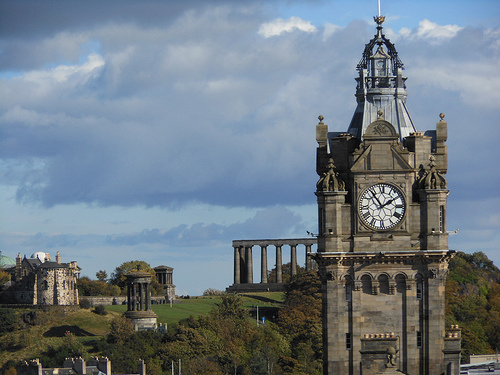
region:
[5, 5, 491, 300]
A blue, cloudy sky.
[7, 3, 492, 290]
Blue sky with grey and white clouds.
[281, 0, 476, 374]
A clock tower.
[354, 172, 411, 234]
Clock reading 1:55 p.m.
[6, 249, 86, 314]
Historic building in the background.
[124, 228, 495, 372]
Trees behind the clock tower.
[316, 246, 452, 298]
Ornamental architecture on the clock tower.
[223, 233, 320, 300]
Historic landmark near the clock tower.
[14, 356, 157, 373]
A row of chimneys.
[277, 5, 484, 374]
A tower featuring a round clock.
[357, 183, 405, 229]
A clock on the tower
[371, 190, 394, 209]
Hands on the clock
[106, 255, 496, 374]
Trees behind the tower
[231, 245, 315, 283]
Pillars behind the trees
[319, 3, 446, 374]
A stone tower in front of trees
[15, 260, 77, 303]
A stone building near the grassy field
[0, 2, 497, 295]
A cloudy sky above the tower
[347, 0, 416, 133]
A tower above the clock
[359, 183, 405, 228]
The clock has roman numerals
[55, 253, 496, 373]
The trees are near the grassy field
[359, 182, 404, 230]
clock on tower side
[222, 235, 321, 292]
tall pillars that are gray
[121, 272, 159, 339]
round pillars in a circle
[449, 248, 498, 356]
trees with green leaves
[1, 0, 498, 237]
clouds with blue sky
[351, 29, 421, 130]
decorative top on tower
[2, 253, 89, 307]
building on top of a hill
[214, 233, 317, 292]
columns on top of hill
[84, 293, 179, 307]
brick wall on hill top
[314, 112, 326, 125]
round sphere on top of tower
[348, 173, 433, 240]
its is 2oclcok on the clock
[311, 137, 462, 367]
the buidling is grey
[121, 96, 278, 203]
clouds are in the sky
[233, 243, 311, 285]
the pillars are six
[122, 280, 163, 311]
the pillars are four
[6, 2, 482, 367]
the scene is outdoors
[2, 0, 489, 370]
the photo was taken in the afternoon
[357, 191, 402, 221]
the clock handle is black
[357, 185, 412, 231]
the numbers are roman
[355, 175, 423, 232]
the clock is circular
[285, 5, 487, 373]
structure with clock on it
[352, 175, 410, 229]
clock on side of structure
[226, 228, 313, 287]
structure with several columns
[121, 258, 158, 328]
gazebo like structure in field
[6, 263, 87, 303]
castle like structure in field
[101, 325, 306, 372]
area with several trees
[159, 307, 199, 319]
field with green grass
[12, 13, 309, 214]
sky with clouds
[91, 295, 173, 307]
wall surrounding an area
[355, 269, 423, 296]
arched structures on tower